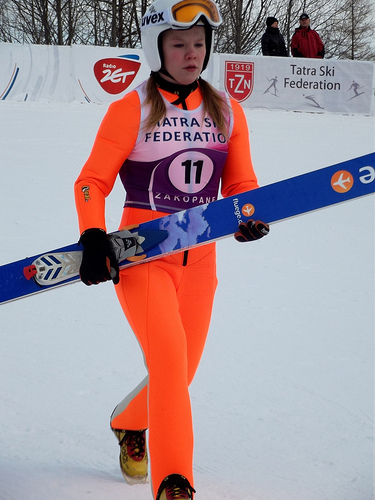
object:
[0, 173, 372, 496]
ground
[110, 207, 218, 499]
pants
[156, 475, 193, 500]
shoes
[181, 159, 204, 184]
"11"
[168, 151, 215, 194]
circle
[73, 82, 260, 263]
shirt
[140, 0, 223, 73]
helmet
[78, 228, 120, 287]
glove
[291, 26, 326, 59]
jacket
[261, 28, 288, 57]
jacket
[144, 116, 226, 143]
letters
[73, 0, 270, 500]
person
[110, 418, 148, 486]
shoe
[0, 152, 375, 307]
board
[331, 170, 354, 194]
circle